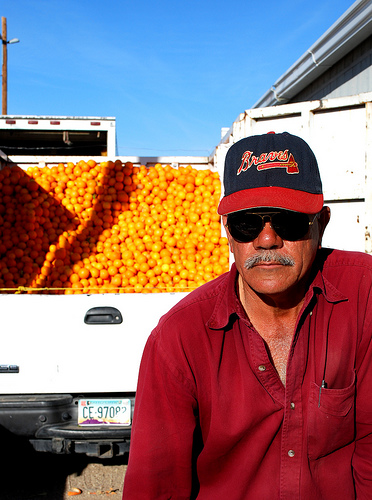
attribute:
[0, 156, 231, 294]
oranges — lot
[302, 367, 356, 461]
pocket — Red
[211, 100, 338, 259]
cap — red, black , baseball cap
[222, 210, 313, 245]
sunglasses — Black 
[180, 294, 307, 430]
shirt — red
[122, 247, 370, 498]
shirt — red, man's shirt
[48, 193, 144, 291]
fruits — citrusy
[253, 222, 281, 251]
nose — red